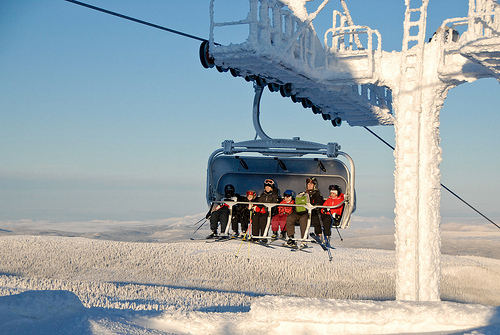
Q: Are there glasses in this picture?
A: No, there are no glasses.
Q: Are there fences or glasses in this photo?
A: No, there are no glasses or fences.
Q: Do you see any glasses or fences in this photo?
A: No, there are no glasses or fences.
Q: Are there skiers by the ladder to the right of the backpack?
A: Yes, there is a skier by the ladder.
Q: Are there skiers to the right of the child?
A: Yes, there is a skier to the right of the child.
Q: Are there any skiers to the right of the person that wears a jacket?
A: Yes, there is a skier to the right of the child.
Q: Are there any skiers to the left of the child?
A: No, the skier is to the right of the child.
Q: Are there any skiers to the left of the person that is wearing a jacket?
A: No, the skier is to the right of the child.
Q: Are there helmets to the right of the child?
A: No, there is a skier to the right of the child.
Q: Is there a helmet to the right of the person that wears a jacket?
A: No, there is a skier to the right of the child.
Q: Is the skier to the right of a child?
A: Yes, the skier is to the right of a child.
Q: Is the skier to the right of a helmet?
A: No, the skier is to the right of a child.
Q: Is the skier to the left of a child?
A: No, the skier is to the right of a child.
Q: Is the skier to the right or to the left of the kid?
A: The skier is to the right of the kid.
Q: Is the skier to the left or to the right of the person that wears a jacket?
A: The skier is to the right of the kid.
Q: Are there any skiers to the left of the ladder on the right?
A: Yes, there is a skier to the left of the ladder.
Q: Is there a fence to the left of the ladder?
A: No, there is a skier to the left of the ladder.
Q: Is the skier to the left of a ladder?
A: Yes, the skier is to the left of a ladder.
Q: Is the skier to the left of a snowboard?
A: No, the skier is to the left of a ladder.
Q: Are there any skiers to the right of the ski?
A: Yes, there is a skier to the right of the ski.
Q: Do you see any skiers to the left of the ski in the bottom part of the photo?
A: No, the skier is to the right of the ski.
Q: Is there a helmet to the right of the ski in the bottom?
A: No, there is a skier to the right of the ski.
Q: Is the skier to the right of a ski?
A: Yes, the skier is to the right of a ski.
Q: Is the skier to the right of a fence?
A: No, the skier is to the right of a ski.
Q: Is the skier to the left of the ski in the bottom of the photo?
A: No, the skier is to the right of the ski.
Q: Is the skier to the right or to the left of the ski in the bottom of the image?
A: The skier is to the right of the ski.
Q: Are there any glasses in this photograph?
A: No, there are no glasses.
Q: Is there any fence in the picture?
A: No, there are no fences.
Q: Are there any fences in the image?
A: No, there are no fences.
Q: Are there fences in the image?
A: No, there are no fences.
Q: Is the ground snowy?
A: Yes, the ground is snowy.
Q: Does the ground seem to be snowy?
A: Yes, the ground is snowy.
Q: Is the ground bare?
A: No, the ground is snowy.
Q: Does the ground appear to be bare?
A: No, the ground is snowy.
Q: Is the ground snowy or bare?
A: The ground is snowy.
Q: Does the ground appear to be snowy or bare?
A: The ground is snowy.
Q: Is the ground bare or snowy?
A: The ground is snowy.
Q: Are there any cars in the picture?
A: No, there are no cars.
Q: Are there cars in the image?
A: No, there are no cars.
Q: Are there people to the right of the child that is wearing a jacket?
A: Yes, there is a person to the right of the child.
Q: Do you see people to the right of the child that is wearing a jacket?
A: Yes, there is a person to the right of the child.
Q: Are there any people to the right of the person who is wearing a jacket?
A: Yes, there is a person to the right of the child.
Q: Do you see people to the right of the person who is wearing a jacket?
A: Yes, there is a person to the right of the child.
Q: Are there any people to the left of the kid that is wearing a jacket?
A: No, the person is to the right of the kid.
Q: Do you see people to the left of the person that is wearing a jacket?
A: No, the person is to the right of the kid.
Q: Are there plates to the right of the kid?
A: No, there is a person to the right of the kid.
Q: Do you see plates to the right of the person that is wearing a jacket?
A: No, there is a person to the right of the kid.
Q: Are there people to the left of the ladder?
A: Yes, there is a person to the left of the ladder.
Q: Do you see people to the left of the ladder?
A: Yes, there is a person to the left of the ladder.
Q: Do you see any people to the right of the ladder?
A: No, the person is to the left of the ladder.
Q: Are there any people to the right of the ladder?
A: No, the person is to the left of the ladder.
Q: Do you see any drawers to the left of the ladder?
A: No, there is a person to the left of the ladder.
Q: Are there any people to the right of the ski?
A: Yes, there is a person to the right of the ski.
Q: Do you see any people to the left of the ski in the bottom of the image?
A: No, the person is to the right of the ski.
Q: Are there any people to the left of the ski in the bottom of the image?
A: No, the person is to the right of the ski.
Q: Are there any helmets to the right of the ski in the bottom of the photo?
A: No, there is a person to the right of the ski.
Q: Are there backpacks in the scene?
A: Yes, there is a backpack.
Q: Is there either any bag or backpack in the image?
A: Yes, there is a backpack.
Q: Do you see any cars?
A: No, there are no cars.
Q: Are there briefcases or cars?
A: No, there are no cars or briefcases.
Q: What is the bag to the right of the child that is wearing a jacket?
A: The bag is a backpack.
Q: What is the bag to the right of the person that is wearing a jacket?
A: The bag is a backpack.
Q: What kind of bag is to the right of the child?
A: The bag is a backpack.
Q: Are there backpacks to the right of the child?
A: Yes, there is a backpack to the right of the child.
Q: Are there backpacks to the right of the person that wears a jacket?
A: Yes, there is a backpack to the right of the child.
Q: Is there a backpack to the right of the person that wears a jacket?
A: Yes, there is a backpack to the right of the child.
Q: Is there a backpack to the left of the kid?
A: No, the backpack is to the right of the kid.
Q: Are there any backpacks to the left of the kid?
A: No, the backpack is to the right of the kid.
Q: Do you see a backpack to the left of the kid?
A: No, the backpack is to the right of the kid.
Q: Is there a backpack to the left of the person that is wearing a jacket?
A: No, the backpack is to the right of the kid.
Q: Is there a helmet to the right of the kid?
A: No, there is a backpack to the right of the kid.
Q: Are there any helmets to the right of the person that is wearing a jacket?
A: No, there is a backpack to the right of the kid.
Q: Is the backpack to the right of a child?
A: Yes, the backpack is to the right of a child.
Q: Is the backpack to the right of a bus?
A: No, the backpack is to the right of a child.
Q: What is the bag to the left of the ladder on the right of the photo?
A: The bag is a backpack.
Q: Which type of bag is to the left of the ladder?
A: The bag is a backpack.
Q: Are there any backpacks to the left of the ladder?
A: Yes, there is a backpack to the left of the ladder.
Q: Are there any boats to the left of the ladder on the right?
A: No, there is a backpack to the left of the ladder.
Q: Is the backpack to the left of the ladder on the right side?
A: Yes, the backpack is to the left of the ladder.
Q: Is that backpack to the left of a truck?
A: No, the backpack is to the left of the ladder.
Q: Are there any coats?
A: Yes, there is a coat.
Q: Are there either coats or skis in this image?
A: Yes, there is a coat.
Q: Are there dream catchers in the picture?
A: No, there are no dream catchers.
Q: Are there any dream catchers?
A: No, there are no dream catchers.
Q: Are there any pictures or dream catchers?
A: No, there are no dream catchers or pictures.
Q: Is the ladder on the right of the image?
A: Yes, the ladder is on the right of the image.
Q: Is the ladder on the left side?
A: No, the ladder is on the right of the image.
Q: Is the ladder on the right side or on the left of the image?
A: The ladder is on the right of the image.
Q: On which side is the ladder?
A: The ladder is on the right of the image.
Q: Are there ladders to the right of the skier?
A: Yes, there is a ladder to the right of the skier.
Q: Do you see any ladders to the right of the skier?
A: Yes, there is a ladder to the right of the skier.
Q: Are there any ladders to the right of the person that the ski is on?
A: Yes, there is a ladder to the right of the skier.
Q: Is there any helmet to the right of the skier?
A: No, there is a ladder to the right of the skier.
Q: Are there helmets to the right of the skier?
A: No, there is a ladder to the right of the skier.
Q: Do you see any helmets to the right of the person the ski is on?
A: No, there is a ladder to the right of the skier.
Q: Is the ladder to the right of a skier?
A: Yes, the ladder is to the right of a skier.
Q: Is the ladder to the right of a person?
A: Yes, the ladder is to the right of a person.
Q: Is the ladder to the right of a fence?
A: No, the ladder is to the right of a person.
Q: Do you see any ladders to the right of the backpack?
A: Yes, there is a ladder to the right of the backpack.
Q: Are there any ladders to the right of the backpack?
A: Yes, there is a ladder to the right of the backpack.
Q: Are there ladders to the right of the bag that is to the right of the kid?
A: Yes, there is a ladder to the right of the backpack.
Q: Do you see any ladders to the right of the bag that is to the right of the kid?
A: Yes, there is a ladder to the right of the backpack.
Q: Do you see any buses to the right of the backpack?
A: No, there is a ladder to the right of the backpack.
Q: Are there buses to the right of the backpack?
A: No, there is a ladder to the right of the backpack.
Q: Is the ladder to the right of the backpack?
A: Yes, the ladder is to the right of the backpack.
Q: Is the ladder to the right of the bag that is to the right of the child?
A: Yes, the ladder is to the right of the backpack.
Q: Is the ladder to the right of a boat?
A: No, the ladder is to the right of the backpack.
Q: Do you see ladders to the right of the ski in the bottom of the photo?
A: Yes, there is a ladder to the right of the ski.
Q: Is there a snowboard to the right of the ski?
A: No, there is a ladder to the right of the ski.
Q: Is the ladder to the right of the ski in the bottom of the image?
A: Yes, the ladder is to the right of the ski.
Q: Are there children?
A: Yes, there is a child.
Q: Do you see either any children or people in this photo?
A: Yes, there is a child.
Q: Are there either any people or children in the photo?
A: Yes, there is a child.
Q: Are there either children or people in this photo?
A: Yes, there is a child.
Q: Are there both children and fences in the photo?
A: No, there is a child but no fences.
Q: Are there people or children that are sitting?
A: Yes, the child is sitting.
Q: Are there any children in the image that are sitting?
A: Yes, there is a child that is sitting.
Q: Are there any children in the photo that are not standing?
A: Yes, there is a child that is sitting.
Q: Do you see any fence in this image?
A: No, there are no fences.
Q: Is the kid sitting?
A: Yes, the kid is sitting.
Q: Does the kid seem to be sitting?
A: Yes, the kid is sitting.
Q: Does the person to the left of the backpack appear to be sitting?
A: Yes, the kid is sitting.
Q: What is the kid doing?
A: The kid is sitting.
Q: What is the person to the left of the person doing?
A: The kid is sitting.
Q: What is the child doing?
A: The kid is sitting.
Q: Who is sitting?
A: The child is sitting.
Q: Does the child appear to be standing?
A: No, the child is sitting.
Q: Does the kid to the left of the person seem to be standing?
A: No, the kid is sitting.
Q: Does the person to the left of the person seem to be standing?
A: No, the kid is sitting.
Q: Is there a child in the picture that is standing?
A: No, there is a child but he is sitting.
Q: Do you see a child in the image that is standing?
A: No, there is a child but he is sitting.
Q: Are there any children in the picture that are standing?
A: No, there is a child but he is sitting.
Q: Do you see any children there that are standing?
A: No, there is a child but he is sitting.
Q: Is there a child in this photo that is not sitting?
A: No, there is a child but he is sitting.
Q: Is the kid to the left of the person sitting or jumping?
A: The child is sitting.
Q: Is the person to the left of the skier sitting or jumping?
A: The child is sitting.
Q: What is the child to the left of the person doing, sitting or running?
A: The child is sitting.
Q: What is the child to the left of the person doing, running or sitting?
A: The child is sitting.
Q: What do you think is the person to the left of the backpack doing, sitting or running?
A: The child is sitting.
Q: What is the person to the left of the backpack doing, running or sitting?
A: The child is sitting.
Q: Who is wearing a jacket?
A: The kid is wearing a jacket.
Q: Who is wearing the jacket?
A: The kid is wearing a jacket.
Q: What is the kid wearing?
A: The kid is wearing a jacket.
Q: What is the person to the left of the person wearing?
A: The kid is wearing a jacket.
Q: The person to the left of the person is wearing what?
A: The kid is wearing a jacket.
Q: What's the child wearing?
A: The kid is wearing a jacket.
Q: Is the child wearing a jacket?
A: Yes, the child is wearing a jacket.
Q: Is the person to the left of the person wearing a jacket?
A: Yes, the child is wearing a jacket.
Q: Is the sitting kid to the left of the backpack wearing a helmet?
A: No, the kid is wearing a jacket.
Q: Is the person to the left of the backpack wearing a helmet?
A: No, the kid is wearing a jacket.